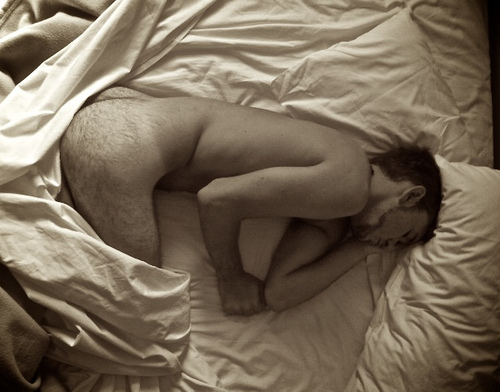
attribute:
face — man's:
[355, 215, 440, 253]